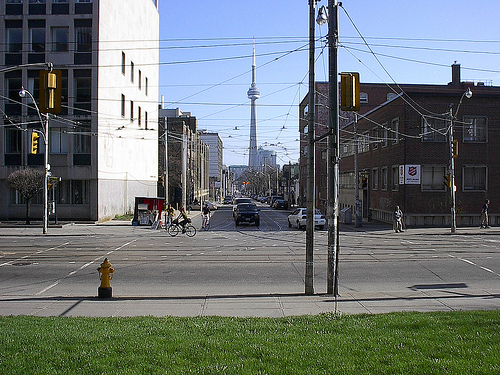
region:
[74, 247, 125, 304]
yellow fire hydrant along sidewalk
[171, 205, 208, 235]
person crossing street on bike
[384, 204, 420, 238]
person standing along sidewalk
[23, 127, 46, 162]
traffic light with yellow painted cover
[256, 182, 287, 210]
cars parked along street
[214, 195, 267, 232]
people sitting in vehicles at traffic light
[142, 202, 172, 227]
people walking along street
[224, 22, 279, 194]
tall building in the distance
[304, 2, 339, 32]
street light hanging off utility pole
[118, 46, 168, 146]
windows overlooking the street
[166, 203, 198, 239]
A person riding a bike.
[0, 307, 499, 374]
Some bright green grass.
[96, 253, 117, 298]
A yellow fire hydrant.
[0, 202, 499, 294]
A large traffic intersection.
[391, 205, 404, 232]
A man standing around.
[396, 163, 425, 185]
Red and white sign.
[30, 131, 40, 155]
A hanging traffic signal.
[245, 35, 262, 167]
The seattle space needle.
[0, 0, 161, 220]
A large white building.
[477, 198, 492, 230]
A person walking around.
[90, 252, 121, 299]
a yellow fire hydrant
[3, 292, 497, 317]
this is a city sidewalk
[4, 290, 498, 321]
this is a sidewalk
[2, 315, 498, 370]
this is a grass lawn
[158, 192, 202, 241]
a person riding a bicycle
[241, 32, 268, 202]
this is a tower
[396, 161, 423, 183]
this sign features the Salvation Army logo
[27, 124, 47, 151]
this is a stoplight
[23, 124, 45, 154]
the stoplight is yellow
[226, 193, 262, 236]
cars stopped at an intersection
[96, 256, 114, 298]
the yellow fire hydrant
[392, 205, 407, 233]
the person on the sidewalk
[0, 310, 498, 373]
the lush green grass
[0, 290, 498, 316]
the sidewalk next to the lush green grass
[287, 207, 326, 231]
the white car on the road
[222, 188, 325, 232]
the cars on the road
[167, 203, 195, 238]
the bike on the road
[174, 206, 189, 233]
the person riding a bike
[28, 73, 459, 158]
the traffic lights above the road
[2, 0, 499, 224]
the buildings on the sides of the road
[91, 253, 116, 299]
Yellow fire hydrant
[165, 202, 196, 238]
Person riding bicycle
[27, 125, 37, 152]
Street traffic light signal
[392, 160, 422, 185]
White and red Salvation Army sign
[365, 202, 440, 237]
Person standing on street corner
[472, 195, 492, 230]
Person walking wearing tan pants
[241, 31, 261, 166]
Tall pointed building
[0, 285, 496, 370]
Green grass next to sidewalk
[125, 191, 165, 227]
Corner red newstand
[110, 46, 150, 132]
Eight building windows